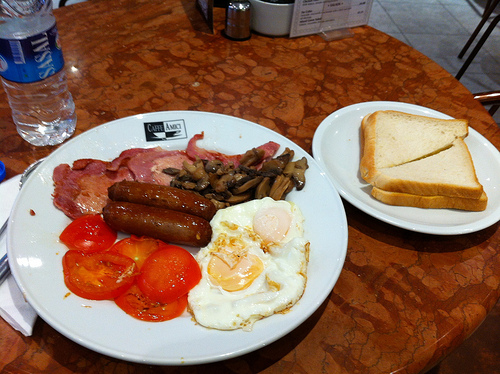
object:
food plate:
[309, 99, 499, 236]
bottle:
[0, 0, 78, 149]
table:
[0, 1, 499, 374]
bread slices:
[359, 109, 483, 199]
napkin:
[0, 171, 36, 339]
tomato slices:
[135, 243, 203, 305]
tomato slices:
[62, 248, 139, 301]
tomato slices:
[58, 212, 118, 255]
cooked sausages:
[101, 199, 213, 249]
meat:
[50, 160, 137, 221]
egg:
[187, 196, 312, 331]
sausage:
[106, 178, 216, 222]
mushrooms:
[254, 175, 273, 200]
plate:
[3, 109, 349, 367]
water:
[0, 0, 78, 148]